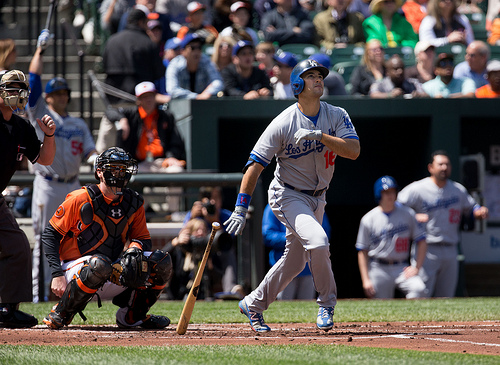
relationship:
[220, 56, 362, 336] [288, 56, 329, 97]
batter wearing helmet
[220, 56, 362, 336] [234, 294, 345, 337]
batter wearing shoes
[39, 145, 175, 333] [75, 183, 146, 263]
catcher wearing vest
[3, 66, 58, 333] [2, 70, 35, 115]
umpire wearing mask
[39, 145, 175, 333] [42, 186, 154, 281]
catcher wearing shirt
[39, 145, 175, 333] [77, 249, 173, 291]
catcher wearing knee pads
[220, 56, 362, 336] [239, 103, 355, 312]
batter wearing uniform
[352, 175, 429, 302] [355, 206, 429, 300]
player wearing uniform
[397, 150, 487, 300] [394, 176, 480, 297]
player wearing uniform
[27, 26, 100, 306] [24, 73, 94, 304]
player wearing uniform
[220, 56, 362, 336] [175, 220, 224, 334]
batter drops baseball bat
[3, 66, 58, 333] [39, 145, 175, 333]
umpire behind catcher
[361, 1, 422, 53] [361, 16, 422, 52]
woman wearing clothes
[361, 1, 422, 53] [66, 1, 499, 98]
woman sitting in audience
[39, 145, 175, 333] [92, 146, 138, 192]
catcher wearing face mask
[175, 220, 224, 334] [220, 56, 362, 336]
baseball bat next to batter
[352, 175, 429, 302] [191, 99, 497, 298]
player in dugout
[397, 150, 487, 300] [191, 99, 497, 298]
player in dugout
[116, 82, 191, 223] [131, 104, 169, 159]
coach wearing shirt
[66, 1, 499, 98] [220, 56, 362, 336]
audience watching batter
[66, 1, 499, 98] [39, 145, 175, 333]
audience watching catcher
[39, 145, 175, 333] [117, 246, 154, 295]
catcher wearing mitt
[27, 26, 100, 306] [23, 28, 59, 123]
player has arm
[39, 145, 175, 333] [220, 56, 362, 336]
catcher behind batter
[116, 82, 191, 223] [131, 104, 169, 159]
coach has shirt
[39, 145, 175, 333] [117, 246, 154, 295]
catcher has mitt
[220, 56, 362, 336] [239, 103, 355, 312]
batter has uniform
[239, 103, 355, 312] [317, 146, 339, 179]
uniform has number